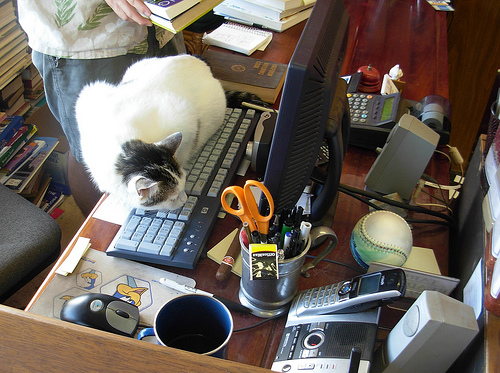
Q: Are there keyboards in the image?
A: Yes, there is a keyboard.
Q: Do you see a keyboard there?
A: Yes, there is a keyboard.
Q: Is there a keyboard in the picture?
A: Yes, there is a keyboard.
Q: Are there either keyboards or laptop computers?
A: Yes, there is a keyboard.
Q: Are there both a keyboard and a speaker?
A: Yes, there are both a keyboard and a speaker.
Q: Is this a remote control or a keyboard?
A: This is a keyboard.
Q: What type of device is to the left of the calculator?
A: The device is a keyboard.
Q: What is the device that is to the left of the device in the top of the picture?
A: The device is a keyboard.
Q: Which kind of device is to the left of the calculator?
A: The device is a keyboard.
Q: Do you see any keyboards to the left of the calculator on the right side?
A: Yes, there is a keyboard to the left of the calculator.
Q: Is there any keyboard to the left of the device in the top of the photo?
A: Yes, there is a keyboard to the left of the calculator.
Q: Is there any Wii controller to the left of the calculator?
A: No, there is a keyboard to the left of the calculator.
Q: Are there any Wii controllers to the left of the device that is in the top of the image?
A: No, there is a keyboard to the left of the calculator.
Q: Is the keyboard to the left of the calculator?
A: Yes, the keyboard is to the left of the calculator.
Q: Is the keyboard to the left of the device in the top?
A: Yes, the keyboard is to the left of the calculator.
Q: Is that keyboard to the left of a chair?
A: No, the keyboard is to the left of the calculator.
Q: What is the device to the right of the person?
A: The device is a keyboard.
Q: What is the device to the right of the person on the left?
A: The device is a keyboard.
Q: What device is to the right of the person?
A: The device is a keyboard.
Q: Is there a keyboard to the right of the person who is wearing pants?
A: Yes, there is a keyboard to the right of the person.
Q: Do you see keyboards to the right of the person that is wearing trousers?
A: Yes, there is a keyboard to the right of the person.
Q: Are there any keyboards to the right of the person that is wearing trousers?
A: Yes, there is a keyboard to the right of the person.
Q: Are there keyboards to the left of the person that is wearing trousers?
A: No, the keyboard is to the right of the person.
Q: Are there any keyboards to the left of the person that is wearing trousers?
A: No, the keyboard is to the right of the person.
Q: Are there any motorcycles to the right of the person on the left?
A: No, there is a keyboard to the right of the person.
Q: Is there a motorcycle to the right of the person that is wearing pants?
A: No, there is a keyboard to the right of the person.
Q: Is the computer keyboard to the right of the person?
A: Yes, the keyboard is to the right of the person.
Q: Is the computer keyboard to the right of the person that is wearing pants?
A: Yes, the keyboard is to the right of the person.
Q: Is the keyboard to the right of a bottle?
A: No, the keyboard is to the right of the person.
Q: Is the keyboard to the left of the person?
A: No, the keyboard is to the right of the person.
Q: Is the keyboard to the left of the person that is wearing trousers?
A: No, the keyboard is to the right of the person.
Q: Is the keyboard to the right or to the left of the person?
A: The keyboard is to the right of the person.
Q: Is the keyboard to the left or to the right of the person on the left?
A: The keyboard is to the right of the person.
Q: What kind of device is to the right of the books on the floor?
A: The device is a keyboard.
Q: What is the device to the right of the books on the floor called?
A: The device is a keyboard.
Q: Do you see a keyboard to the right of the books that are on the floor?
A: Yes, there is a keyboard to the right of the books.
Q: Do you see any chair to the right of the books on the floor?
A: No, there is a keyboard to the right of the books.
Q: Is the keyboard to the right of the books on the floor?
A: Yes, the keyboard is to the right of the books.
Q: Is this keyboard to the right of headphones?
A: No, the keyboard is to the right of the books.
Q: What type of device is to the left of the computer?
A: The device is a keyboard.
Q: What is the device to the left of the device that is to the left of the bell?
A: The device is a keyboard.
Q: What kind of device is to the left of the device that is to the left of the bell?
A: The device is a keyboard.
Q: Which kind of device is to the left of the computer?
A: The device is a keyboard.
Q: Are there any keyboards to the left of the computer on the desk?
A: Yes, there is a keyboard to the left of the computer.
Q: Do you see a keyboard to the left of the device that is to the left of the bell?
A: Yes, there is a keyboard to the left of the computer.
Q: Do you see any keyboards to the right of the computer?
A: No, the keyboard is to the left of the computer.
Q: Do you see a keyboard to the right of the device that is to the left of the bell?
A: No, the keyboard is to the left of the computer.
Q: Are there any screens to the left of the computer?
A: No, there is a keyboard to the left of the computer.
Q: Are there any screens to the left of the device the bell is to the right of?
A: No, there is a keyboard to the left of the computer.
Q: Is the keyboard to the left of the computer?
A: Yes, the keyboard is to the left of the computer.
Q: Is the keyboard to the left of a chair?
A: No, the keyboard is to the left of the computer.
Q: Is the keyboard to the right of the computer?
A: No, the keyboard is to the left of the computer.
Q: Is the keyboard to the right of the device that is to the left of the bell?
A: No, the keyboard is to the left of the computer.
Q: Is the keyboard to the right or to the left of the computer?
A: The keyboard is to the left of the computer.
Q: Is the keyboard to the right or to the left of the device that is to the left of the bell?
A: The keyboard is to the left of the computer.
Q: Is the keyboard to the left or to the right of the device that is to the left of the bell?
A: The keyboard is to the left of the computer.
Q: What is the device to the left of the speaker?
A: The device is a keyboard.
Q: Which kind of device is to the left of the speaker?
A: The device is a keyboard.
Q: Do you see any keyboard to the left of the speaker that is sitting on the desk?
A: Yes, there is a keyboard to the left of the speaker.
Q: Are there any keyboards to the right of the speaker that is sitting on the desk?
A: No, the keyboard is to the left of the speaker.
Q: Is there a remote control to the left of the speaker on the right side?
A: No, there is a keyboard to the left of the speaker.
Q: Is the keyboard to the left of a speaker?
A: Yes, the keyboard is to the left of a speaker.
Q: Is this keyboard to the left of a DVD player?
A: No, the keyboard is to the left of a speaker.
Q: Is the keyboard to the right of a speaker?
A: No, the keyboard is to the left of a speaker.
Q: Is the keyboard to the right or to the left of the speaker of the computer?
A: The keyboard is to the left of the speaker.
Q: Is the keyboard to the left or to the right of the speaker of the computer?
A: The keyboard is to the left of the speaker.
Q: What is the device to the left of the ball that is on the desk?
A: The device is a keyboard.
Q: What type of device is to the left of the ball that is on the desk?
A: The device is a keyboard.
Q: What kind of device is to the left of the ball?
A: The device is a keyboard.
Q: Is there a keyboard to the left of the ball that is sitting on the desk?
A: Yes, there is a keyboard to the left of the ball.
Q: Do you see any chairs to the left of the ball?
A: No, there is a keyboard to the left of the ball.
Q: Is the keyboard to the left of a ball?
A: Yes, the keyboard is to the left of a ball.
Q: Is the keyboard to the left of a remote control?
A: No, the keyboard is to the left of a ball.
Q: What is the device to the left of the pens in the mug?
A: The device is a keyboard.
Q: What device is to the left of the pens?
A: The device is a keyboard.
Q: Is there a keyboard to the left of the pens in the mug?
A: Yes, there is a keyboard to the left of the pens.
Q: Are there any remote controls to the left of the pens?
A: No, there is a keyboard to the left of the pens.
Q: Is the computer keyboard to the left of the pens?
A: Yes, the keyboard is to the left of the pens.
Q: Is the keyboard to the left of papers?
A: No, the keyboard is to the left of the pens.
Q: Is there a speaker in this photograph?
A: Yes, there is a speaker.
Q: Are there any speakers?
A: Yes, there is a speaker.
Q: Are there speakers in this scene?
A: Yes, there is a speaker.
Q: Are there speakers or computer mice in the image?
A: Yes, there is a speaker.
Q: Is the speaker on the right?
A: Yes, the speaker is on the right of the image.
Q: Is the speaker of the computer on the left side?
A: No, the speaker is on the right of the image.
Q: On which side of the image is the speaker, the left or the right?
A: The speaker is on the right of the image.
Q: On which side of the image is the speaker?
A: The speaker is on the right of the image.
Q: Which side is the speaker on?
A: The speaker is on the right of the image.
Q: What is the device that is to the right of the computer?
A: The device is a speaker.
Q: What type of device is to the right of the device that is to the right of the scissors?
A: The device is a speaker.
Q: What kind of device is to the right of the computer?
A: The device is a speaker.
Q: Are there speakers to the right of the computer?
A: Yes, there is a speaker to the right of the computer.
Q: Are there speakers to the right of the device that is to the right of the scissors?
A: Yes, there is a speaker to the right of the computer.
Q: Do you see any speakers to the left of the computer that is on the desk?
A: No, the speaker is to the right of the computer.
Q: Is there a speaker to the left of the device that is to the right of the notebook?
A: No, the speaker is to the right of the computer.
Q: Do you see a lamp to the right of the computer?
A: No, there is a speaker to the right of the computer.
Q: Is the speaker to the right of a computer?
A: Yes, the speaker is to the right of a computer.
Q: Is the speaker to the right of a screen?
A: No, the speaker is to the right of a computer.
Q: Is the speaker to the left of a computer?
A: No, the speaker is to the right of a computer.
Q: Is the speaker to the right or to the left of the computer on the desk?
A: The speaker is to the right of the computer.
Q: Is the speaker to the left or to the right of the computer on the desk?
A: The speaker is to the right of the computer.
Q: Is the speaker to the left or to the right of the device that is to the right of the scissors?
A: The speaker is to the right of the computer.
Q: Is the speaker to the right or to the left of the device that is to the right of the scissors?
A: The speaker is to the right of the computer.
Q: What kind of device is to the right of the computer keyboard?
A: The device is a speaker.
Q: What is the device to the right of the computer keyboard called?
A: The device is a speaker.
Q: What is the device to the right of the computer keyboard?
A: The device is a speaker.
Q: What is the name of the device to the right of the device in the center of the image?
A: The device is a speaker.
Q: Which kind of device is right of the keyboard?
A: The device is a speaker.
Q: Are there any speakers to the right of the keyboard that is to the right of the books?
A: Yes, there is a speaker to the right of the keyboard.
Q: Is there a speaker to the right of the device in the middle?
A: Yes, there is a speaker to the right of the keyboard.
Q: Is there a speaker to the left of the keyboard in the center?
A: No, the speaker is to the right of the keyboard.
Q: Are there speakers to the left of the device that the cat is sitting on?
A: No, the speaker is to the right of the keyboard.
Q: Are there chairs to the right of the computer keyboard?
A: No, there is a speaker to the right of the keyboard.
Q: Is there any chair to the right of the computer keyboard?
A: No, there is a speaker to the right of the keyboard.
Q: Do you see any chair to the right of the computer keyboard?
A: No, there is a speaker to the right of the keyboard.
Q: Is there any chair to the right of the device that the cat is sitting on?
A: No, there is a speaker to the right of the keyboard.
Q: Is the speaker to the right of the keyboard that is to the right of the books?
A: Yes, the speaker is to the right of the keyboard.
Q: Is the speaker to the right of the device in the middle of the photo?
A: Yes, the speaker is to the right of the keyboard.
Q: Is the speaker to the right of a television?
A: No, the speaker is to the right of the keyboard.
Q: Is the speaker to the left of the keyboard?
A: No, the speaker is to the right of the keyboard.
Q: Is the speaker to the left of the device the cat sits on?
A: No, the speaker is to the right of the keyboard.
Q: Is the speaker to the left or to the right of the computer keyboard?
A: The speaker is to the right of the keyboard.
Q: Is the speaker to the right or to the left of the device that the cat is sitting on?
A: The speaker is to the right of the keyboard.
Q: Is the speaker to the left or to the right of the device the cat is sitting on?
A: The speaker is to the right of the keyboard.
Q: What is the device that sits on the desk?
A: The device is a speaker.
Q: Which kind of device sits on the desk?
A: The device is a speaker.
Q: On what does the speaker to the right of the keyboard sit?
A: The speaker sits on the desk.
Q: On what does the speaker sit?
A: The speaker sits on the desk.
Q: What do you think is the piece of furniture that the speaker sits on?
A: The piece of furniture is a desk.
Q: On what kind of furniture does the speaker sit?
A: The speaker sits on the desk.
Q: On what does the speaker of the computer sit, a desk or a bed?
A: The speaker sits on a desk.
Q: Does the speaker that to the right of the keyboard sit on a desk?
A: Yes, the speaker sits on a desk.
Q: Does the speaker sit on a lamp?
A: No, the speaker sits on a desk.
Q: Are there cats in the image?
A: Yes, there is a cat.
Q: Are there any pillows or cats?
A: Yes, there is a cat.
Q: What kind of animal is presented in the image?
A: The animal is a cat.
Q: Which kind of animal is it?
A: The animal is a cat.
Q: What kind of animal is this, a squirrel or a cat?
A: That is a cat.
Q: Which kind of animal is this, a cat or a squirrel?
A: That is a cat.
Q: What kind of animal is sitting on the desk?
A: The animal is a cat.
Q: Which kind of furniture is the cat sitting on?
A: The cat is sitting on the desk.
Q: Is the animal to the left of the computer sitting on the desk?
A: Yes, the cat is sitting on the desk.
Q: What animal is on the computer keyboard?
A: The cat is on the keyboard.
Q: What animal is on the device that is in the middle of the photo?
A: The cat is on the keyboard.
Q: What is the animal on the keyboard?
A: The animal is a cat.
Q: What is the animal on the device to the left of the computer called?
A: The animal is a cat.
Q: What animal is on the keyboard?
A: The animal is a cat.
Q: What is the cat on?
A: The cat is on the keyboard.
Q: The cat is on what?
A: The cat is on the keyboard.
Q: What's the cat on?
A: The cat is on the keyboard.